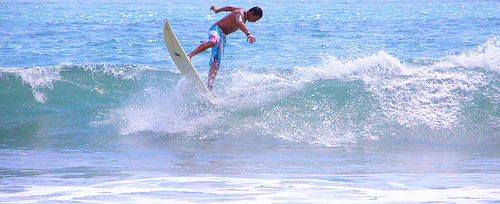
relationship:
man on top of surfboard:
[190, 7, 262, 87] [160, 24, 207, 111]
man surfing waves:
[190, 7, 262, 87] [4, 56, 498, 152]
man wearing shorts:
[190, 7, 262, 87] [203, 28, 226, 66]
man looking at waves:
[190, 7, 262, 87] [4, 56, 498, 152]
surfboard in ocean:
[160, 24, 207, 111] [3, 4, 495, 201]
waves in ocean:
[4, 56, 498, 152] [3, 4, 495, 201]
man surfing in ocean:
[190, 7, 262, 87] [3, 4, 495, 201]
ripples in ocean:
[5, 18, 481, 52] [3, 4, 495, 201]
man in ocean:
[190, 7, 262, 87] [3, 4, 495, 201]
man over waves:
[190, 7, 262, 87] [4, 56, 498, 152]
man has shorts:
[190, 7, 262, 87] [203, 28, 226, 66]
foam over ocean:
[292, 42, 499, 125] [3, 4, 495, 201]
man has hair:
[190, 7, 262, 87] [249, 6, 263, 18]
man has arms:
[190, 7, 262, 87] [209, 3, 253, 45]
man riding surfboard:
[190, 7, 262, 87] [160, 24, 207, 111]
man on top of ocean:
[190, 7, 262, 87] [3, 4, 495, 201]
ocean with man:
[3, 4, 495, 201] [190, 7, 262, 87]